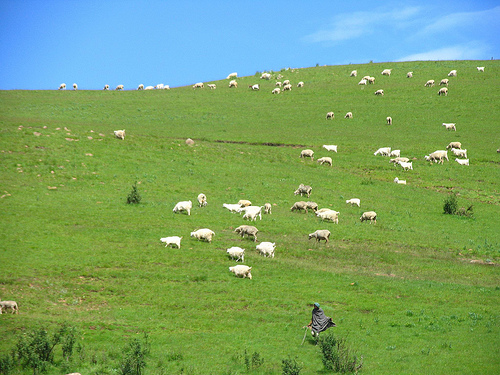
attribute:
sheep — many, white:
[150, 185, 284, 281]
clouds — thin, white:
[316, 8, 478, 40]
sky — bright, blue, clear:
[252, 6, 290, 28]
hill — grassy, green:
[177, 100, 221, 126]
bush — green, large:
[440, 190, 476, 222]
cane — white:
[299, 323, 309, 346]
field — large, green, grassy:
[219, 104, 286, 142]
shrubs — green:
[10, 319, 158, 365]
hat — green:
[312, 301, 322, 310]